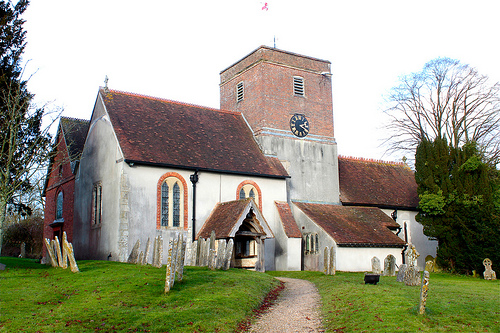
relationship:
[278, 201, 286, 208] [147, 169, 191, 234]
brick around window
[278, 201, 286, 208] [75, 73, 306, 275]
brick on building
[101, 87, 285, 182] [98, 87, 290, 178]
red brick on roof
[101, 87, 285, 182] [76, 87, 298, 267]
red brick on building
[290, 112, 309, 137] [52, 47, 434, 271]
clock on building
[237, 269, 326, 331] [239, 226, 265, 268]
path to door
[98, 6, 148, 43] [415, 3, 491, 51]
part of sky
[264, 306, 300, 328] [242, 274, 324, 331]
part of footpath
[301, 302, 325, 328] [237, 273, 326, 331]
edge of path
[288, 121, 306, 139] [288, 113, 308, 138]
part of clock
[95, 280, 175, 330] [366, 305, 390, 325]
part of grass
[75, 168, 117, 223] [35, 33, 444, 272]
edge of church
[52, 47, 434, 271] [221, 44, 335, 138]
building with brick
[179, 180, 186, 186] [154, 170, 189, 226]
brick around window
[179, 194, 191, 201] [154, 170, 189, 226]
brick around window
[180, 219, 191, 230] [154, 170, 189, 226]
brick around window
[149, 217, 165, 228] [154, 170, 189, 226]
brick around window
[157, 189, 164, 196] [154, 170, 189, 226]
brick around window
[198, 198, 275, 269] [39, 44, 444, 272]
covered entryway to church